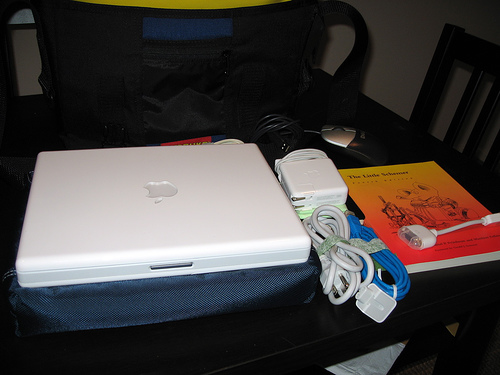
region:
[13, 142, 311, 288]
White Apple laptop on desk top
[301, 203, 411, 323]
folded blue and gray cords on desk top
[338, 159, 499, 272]
orange and yellow book with cord on top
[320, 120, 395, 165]
black and silver computer mouse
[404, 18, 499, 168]
dark wooden chair tucked into table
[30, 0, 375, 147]
black and blue computer bag behind computer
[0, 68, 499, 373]
black wooden desk in room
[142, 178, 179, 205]
apple logo on white laptop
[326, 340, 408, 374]
white piece of paper under table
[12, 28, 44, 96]
tan wall behind table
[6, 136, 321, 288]
A white macbook computer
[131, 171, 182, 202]
A white 'Apple' logo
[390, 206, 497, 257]
A small white charger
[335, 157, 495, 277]
A red/yellow book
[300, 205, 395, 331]
A long white charger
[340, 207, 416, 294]
A coiled up blue cable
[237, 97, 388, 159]
A mouse with a coiled up wire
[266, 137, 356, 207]
The plug-in for a charger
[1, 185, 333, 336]
A blue laptop case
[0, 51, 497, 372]
A black wooden table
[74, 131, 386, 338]
This is a mac computer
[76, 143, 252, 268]
This is a macbook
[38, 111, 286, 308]
This is a laptop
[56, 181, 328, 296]
The laptop is white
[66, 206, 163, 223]
This is the lid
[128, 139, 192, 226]
This is the mac logo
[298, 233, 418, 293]
These are cables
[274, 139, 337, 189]
This is the charger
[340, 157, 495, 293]
This is a book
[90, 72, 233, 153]
This is a black table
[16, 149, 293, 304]
the macbook is white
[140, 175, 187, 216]
There is an apple logo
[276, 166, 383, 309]
The charger is white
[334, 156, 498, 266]
The book is orange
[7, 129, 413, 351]
The macbook is on the table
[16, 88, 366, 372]
The table is black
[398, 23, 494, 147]
The chair is black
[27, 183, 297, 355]
The macbook is sitting on a blue bag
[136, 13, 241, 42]
The chair has a blue stripe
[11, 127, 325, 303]
the laptop is white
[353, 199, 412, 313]
the cord is blue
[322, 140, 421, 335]
the cord is blue